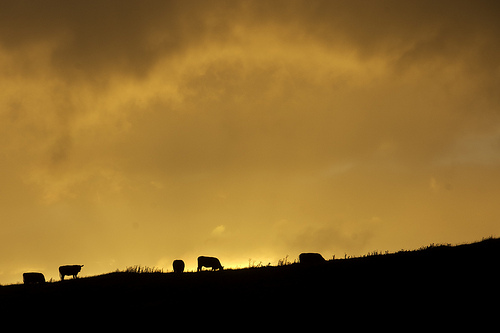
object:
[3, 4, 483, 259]
sky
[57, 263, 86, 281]
animals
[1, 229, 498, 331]
hill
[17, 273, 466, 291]
shadow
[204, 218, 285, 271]
sun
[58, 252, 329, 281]
three cows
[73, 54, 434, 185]
clouds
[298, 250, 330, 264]
last cow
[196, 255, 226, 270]
second cow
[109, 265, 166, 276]
grass